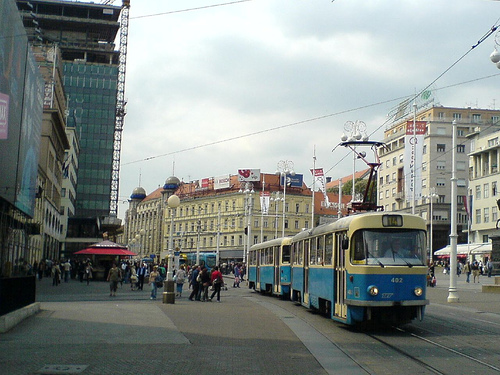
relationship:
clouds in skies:
[171, 82, 313, 224] [116, 0, 500, 189]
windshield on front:
[351, 227, 431, 268] [347, 211, 426, 325]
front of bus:
[347, 211, 426, 325] [235, 208, 434, 334]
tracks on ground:
[325, 332, 455, 372] [10, 261, 498, 372]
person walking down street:
[106, 259, 124, 300] [8, 274, 328, 374]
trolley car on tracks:
[289, 208, 436, 333] [372, 331, 498, 373]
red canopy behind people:
[74, 238, 135, 254] [216, 259, 246, 286]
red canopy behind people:
[74, 238, 135, 254] [177, 258, 225, 303]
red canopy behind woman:
[74, 238, 135, 254] [147, 265, 164, 301]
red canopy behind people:
[74, 238, 135, 254] [36, 252, 94, 284]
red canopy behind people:
[74, 238, 135, 254] [426, 252, 493, 289]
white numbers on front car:
[388, 276, 404, 283] [287, 210, 430, 329]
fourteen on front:
[385, 210, 403, 228] [347, 211, 426, 325]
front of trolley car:
[347, 211, 426, 325] [289, 208, 436, 333]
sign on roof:
[236, 166, 265, 188] [136, 170, 313, 204]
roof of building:
[136, 170, 313, 204] [122, 114, 349, 321]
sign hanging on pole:
[258, 196, 275, 218] [260, 166, 290, 240]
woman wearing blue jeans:
[147, 265, 164, 301] [147, 280, 164, 301]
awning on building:
[427, 238, 497, 259] [433, 129, 498, 279]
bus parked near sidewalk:
[235, 208, 434, 334] [3, 306, 298, 373]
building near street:
[119, 166, 311, 274] [3, 265, 495, 372]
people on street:
[86, 205, 267, 316] [3, 265, 495, 372]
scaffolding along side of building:
[110, 1, 127, 234] [2, 1, 118, 286]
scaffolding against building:
[110, 1, 127, 234] [63, 0, 133, 241]